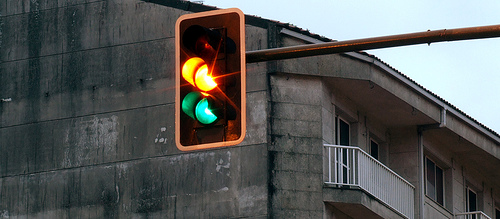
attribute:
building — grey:
[3, 1, 497, 217]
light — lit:
[194, 63, 216, 90]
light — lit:
[195, 100, 216, 123]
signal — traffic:
[171, 3, 254, 151]